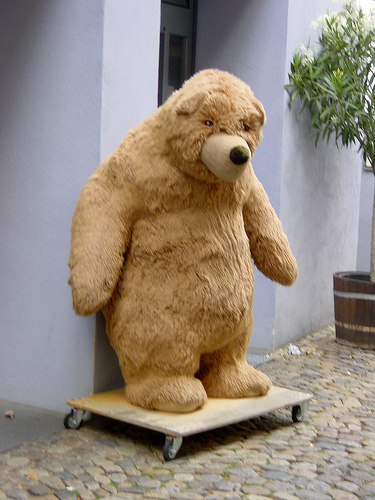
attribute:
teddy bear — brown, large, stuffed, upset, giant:
[68, 66, 293, 413]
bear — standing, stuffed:
[66, 64, 296, 412]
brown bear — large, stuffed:
[138, 80, 265, 304]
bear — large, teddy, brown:
[63, 73, 318, 409]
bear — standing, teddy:
[152, 61, 245, 253]